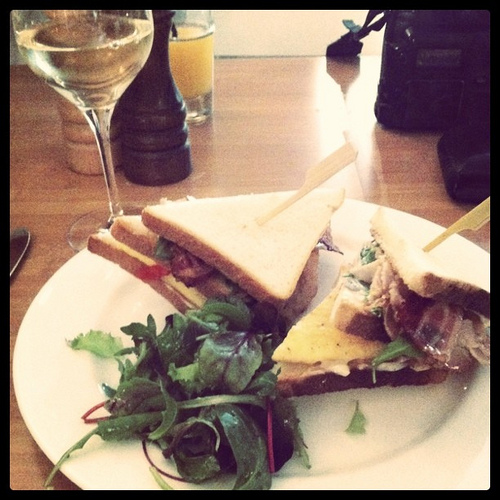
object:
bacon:
[387, 274, 489, 372]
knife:
[9, 227, 32, 288]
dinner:
[36, 144, 491, 492]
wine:
[14, 15, 155, 89]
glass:
[12, 6, 157, 254]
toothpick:
[265, 142, 359, 221]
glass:
[167, 22, 215, 124]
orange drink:
[167, 26, 213, 100]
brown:
[436, 283, 470, 298]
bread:
[86, 230, 209, 319]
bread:
[371, 206, 498, 313]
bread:
[139, 186, 346, 311]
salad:
[43, 297, 313, 490]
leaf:
[367, 333, 423, 386]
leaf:
[341, 394, 371, 438]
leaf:
[67, 327, 124, 362]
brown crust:
[139, 207, 286, 314]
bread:
[109, 216, 237, 301]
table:
[10, 57, 490, 490]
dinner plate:
[9, 196, 492, 490]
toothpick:
[421, 194, 489, 264]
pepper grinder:
[109, 11, 195, 188]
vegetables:
[49, 299, 311, 494]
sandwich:
[83, 184, 345, 343]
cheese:
[269, 273, 385, 381]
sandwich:
[268, 205, 490, 396]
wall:
[213, 5, 385, 57]